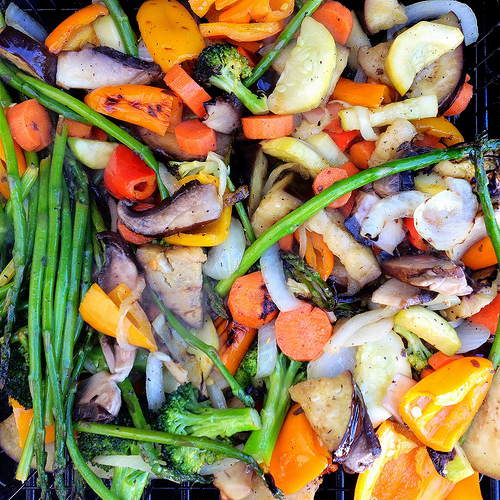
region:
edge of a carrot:
[180, 125, 204, 150]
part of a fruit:
[280, 431, 310, 483]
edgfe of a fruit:
[293, 445, 327, 480]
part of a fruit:
[302, 464, 316, 486]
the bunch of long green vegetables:
[35, 124, 89, 463]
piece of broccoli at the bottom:
[164, 381, 250, 460]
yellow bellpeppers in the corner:
[357, 378, 494, 494]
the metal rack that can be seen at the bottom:
[34, 465, 485, 499]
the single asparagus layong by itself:
[232, 135, 465, 280]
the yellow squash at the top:
[354, 32, 467, 106]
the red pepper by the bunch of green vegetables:
[100, 139, 180, 204]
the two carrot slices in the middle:
[211, 268, 332, 378]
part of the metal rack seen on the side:
[467, 15, 492, 152]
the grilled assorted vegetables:
[23, 41, 454, 462]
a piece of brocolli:
[195, 40, 265, 113]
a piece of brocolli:
[165, 386, 262, 473]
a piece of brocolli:
[82, 420, 152, 498]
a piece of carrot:
[275, 305, 332, 357]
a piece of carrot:
[227, 271, 274, 326]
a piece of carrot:
[6, 97, 49, 152]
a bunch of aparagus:
[0, 113, 95, 498]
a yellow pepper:
[403, 354, 483, 450]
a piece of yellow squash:
[270, 15, 332, 111]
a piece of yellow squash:
[382, 20, 461, 93]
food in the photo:
[79, 52, 394, 314]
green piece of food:
[153, 392, 242, 476]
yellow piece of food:
[405, 355, 478, 442]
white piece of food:
[262, 254, 292, 316]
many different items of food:
[131, 57, 381, 274]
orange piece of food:
[177, 110, 222, 166]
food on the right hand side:
[354, 168, 484, 330]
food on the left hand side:
[0, 124, 140, 317]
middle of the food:
[144, 143, 289, 312]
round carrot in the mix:
[271, 290, 336, 372]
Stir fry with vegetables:
[20, 20, 492, 459]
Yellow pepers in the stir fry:
[354, 355, 476, 480]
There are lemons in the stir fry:
[383, 33, 467, 101]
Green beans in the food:
[30, 195, 82, 420]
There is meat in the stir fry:
[142, 232, 207, 338]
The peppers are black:
[103, 149, 152, 222]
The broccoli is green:
[140, 392, 247, 462]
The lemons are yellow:
[290, 40, 324, 100]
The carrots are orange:
[147, 46, 218, 113]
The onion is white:
[192, 208, 308, 345]